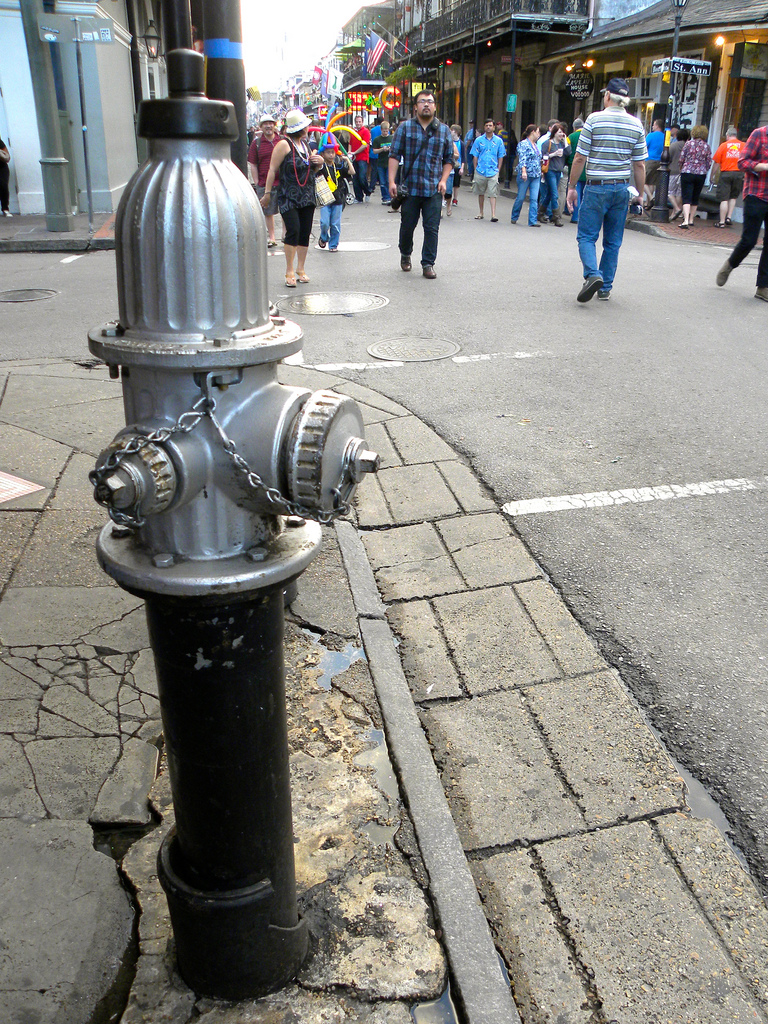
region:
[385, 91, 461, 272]
white person is walking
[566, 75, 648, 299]
white person is walking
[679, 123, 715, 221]
white person is walking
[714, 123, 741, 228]
white person is walking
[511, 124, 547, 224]
white person is walking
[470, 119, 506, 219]
white person is walking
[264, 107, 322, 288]
white person is walking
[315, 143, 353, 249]
white person is walking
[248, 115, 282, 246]
white person is walking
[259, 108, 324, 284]
woman wearing light colored bucket hat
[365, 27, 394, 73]
angled American flag blowing in wind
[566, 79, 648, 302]
man wearing khaki and white striped shirt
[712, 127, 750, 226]
person wearing bright orange shirt with white text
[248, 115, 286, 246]
man wearing solid maroon shirt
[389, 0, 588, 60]
black wrought iron balcony railing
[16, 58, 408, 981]
the hydrant is black and silver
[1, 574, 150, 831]
the sidewalk is cracked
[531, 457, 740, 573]
the street has a white line on it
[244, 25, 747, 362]
people are walking in the street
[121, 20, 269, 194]
the tip of the hydrant is black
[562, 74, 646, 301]
the man is wearing a striped shirt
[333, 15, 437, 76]
a flag is hanging off of the balcony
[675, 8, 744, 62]
the light is on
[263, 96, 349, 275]
the woman is wearing a hat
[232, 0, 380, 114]
the sky is overcast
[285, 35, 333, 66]
a view of sky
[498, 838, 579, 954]
a view of lines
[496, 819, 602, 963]
lines in the road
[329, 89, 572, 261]
a group of people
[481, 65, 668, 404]
a man on the road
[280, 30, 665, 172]
a view of building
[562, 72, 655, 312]
Man in a striped shirt and blue hat.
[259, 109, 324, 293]
Woman in a white hat with red necklace.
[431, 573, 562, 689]
A tile in a floor.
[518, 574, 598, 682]
A tile in a floor.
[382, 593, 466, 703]
A tile in a floor.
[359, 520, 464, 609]
A tile in a floor.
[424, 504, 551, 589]
A tile in a floor.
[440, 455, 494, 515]
A tile in a floor.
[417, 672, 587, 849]
A tile in a floor.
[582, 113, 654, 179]
The shirt is striped.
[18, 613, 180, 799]
Cracks in the sidewalk.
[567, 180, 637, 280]
The man is wearing blue jeans.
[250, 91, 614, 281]
People walking on the street.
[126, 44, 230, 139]
The top of the hydrant is black.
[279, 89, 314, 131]
The woman is wearing a hat.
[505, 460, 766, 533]
The white line on the street.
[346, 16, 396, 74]
A flag hanging from the pole.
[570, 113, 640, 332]
a person walking on the road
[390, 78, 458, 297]
a person walking on the road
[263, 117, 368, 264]
a person walking on the road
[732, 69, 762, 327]
a person walking on the road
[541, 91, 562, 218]
a person walking on the road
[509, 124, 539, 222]
a person walking on the road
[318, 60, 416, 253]
a person walking on the road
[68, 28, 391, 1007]
A silver and black fire hydrant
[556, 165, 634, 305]
A pair of blue jeans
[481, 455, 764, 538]
A white line on the street